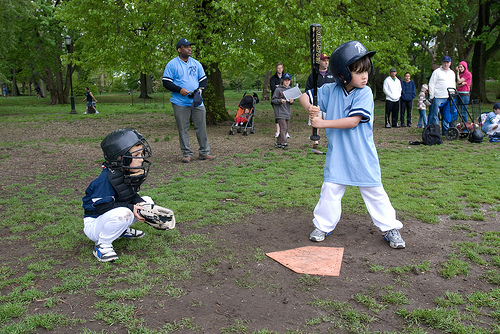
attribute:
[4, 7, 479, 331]
game — ball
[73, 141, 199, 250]
kid — squatting, catcher, in catchers stance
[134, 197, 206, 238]
catchers mitt — catcher's 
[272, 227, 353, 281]
homeplate — orange, Home 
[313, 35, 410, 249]
boy — preparing to swing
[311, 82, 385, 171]
shirt — light blue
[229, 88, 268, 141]
stroller — orange, black, red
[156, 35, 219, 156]
man — watching game, coach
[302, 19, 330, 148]
baseball bat — black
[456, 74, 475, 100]
pink shirt — hooded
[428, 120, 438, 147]
backpack — black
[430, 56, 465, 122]
guy — watching game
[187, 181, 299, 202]
grass — patchy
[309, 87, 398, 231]
uniform — blue, white